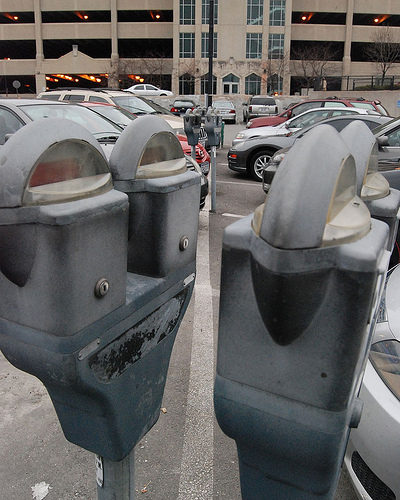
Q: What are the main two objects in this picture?
A: Parking meters.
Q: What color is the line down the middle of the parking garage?
A: White.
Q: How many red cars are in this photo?
A: Two.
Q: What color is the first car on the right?
A: Silver.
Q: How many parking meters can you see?
A: Four.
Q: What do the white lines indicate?
A: Parking space.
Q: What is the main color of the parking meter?
A: Grey.